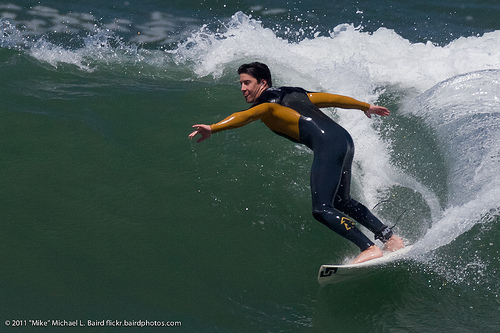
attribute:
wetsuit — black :
[205, 84, 393, 244]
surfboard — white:
[316, 235, 431, 284]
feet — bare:
[340, 231, 414, 256]